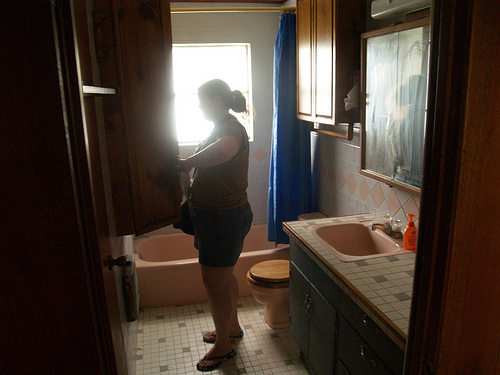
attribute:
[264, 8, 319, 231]
curtain — blue, drawn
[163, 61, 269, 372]
lady — checking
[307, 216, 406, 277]
sink — pink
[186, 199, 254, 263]
shorts — gray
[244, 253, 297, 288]
toilet cover — wooden, brown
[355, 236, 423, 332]
counter — tiled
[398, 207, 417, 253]
bottle — orange